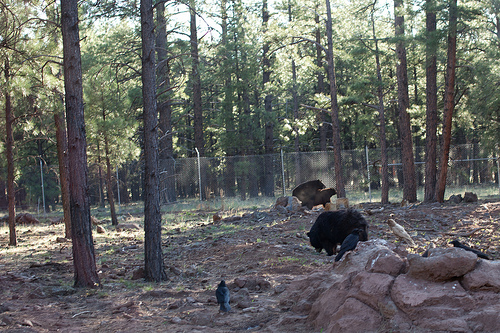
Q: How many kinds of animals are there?
A: Two.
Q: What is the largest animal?
A: A bear.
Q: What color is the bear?
A: Black.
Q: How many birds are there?
A: Three.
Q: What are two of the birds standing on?
A: Stones.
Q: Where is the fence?
A: Along the back.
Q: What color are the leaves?
A: Green.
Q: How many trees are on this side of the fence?
A: Ten.